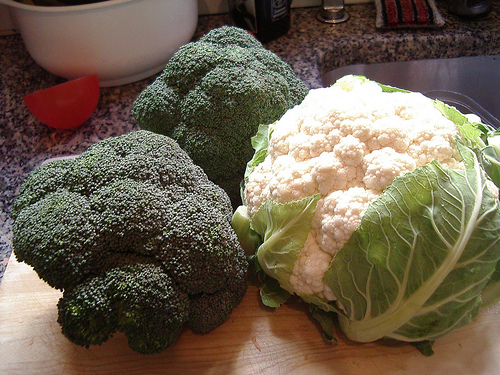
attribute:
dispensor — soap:
[313, 0, 348, 24]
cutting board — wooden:
[5, 227, 497, 374]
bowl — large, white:
[0, 0, 206, 92]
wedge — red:
[22, 72, 99, 127]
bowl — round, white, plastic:
[1, 2, 198, 86]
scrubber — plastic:
[368, 7, 474, 52]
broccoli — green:
[163, 40, 245, 126]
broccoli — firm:
[26, 131, 256, 339]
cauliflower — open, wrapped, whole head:
[228, 60, 499, 362]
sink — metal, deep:
[320, 52, 499, 119]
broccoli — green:
[6, 69, 283, 345]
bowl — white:
[12, 1, 198, 81]